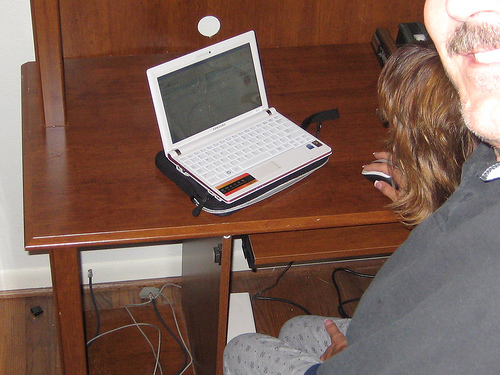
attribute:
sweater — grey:
[303, 141, 495, 372]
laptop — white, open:
[147, 27, 332, 207]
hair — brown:
[372, 32, 479, 229]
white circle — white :
[195, 13, 222, 42]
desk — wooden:
[19, 1, 424, 373]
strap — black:
[301, 105, 344, 127]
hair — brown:
[380, 91, 452, 188]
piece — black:
[28, 301, 43, 319]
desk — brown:
[12, 59, 446, 371]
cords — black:
[78, 256, 388, 373]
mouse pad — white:
[248, 157, 281, 179]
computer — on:
[145, 31, 332, 208]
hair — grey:
[455, 89, 487, 150]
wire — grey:
[134, 284, 166, 305]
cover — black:
[150, 148, 223, 213]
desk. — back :
[23, 212, 169, 247]